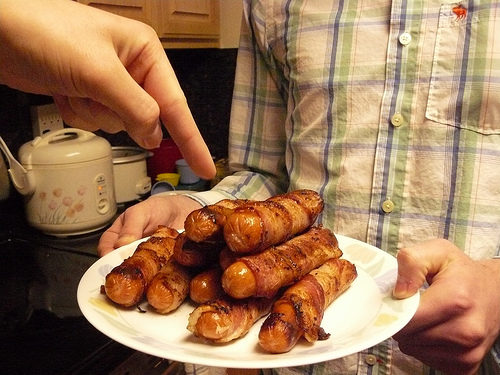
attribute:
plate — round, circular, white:
[340, 292, 388, 347]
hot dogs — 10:
[105, 267, 212, 315]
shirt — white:
[297, 95, 397, 155]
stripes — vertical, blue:
[296, 53, 381, 95]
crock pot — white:
[24, 149, 105, 232]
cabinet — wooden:
[156, 0, 220, 60]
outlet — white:
[30, 102, 64, 137]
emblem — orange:
[450, 0, 471, 30]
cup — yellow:
[148, 172, 188, 193]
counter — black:
[19, 339, 97, 365]